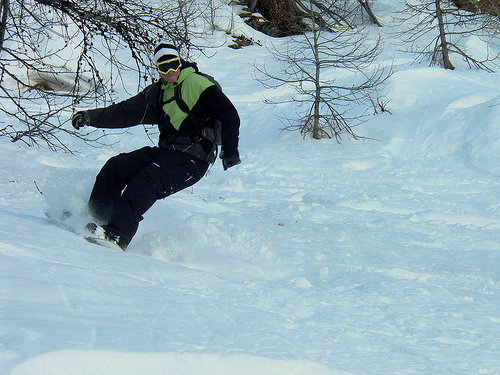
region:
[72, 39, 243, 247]
man on snow board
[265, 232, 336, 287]
white snow on hill side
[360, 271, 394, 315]
white snow on hill side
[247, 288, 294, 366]
white snow on hill side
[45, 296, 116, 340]
white snow on hill side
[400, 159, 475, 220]
white snow on hill side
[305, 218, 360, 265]
white snow on hill side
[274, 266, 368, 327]
white snow on hill side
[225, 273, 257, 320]
white snow on hill side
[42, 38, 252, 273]
snow boarder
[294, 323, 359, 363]
white snow on hill side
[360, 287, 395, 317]
white snow on hill side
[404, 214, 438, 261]
white snow on hill side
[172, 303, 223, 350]
white snow on hill side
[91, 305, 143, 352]
white snow on hill side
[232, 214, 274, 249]
white snow on hill side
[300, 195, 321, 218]
white snow on hill side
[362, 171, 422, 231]
white snow on hill side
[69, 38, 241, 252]
a skier dressed in mostly black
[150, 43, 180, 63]
a blue and white ski hat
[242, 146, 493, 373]
white drifting snow, good for sking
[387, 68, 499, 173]
a white snow drift in background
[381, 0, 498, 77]
a tree in the winter time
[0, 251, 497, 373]
drifting snow, good to ski on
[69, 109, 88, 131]
a black gloved skier's hand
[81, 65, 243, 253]
a black with green skiers outfit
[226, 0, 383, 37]
a bare tree trunk amidst the snow drifts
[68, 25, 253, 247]
young man on snow board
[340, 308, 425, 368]
white snow on hill side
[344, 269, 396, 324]
white snow on hill side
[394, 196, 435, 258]
white snow on hill side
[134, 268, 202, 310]
white snow on hill side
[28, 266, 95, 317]
white snow on hill side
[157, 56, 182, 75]
The yellow and black snow glasses.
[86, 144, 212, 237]
The black snow pants.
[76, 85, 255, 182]
The mans black and green coat.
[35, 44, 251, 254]
man riding snowboard in white snow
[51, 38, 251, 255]
person riding snowboard in white snow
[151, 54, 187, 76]
man wearing black and yellow goggles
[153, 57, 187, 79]
black and yellow goggles worn by man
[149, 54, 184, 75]
black and yellow goggles worn by snowboarder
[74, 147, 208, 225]
black pants worn by man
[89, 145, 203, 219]
black pants worn by snowboarder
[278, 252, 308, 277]
white snow on hill side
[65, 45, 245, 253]
Man in a green and black jacket skiing.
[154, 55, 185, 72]
Goggles on a man skiing in the snow.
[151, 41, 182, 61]
Black and white hat on a man skiing.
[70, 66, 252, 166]
Black and green jacket on a man skiing.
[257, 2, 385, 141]
Leafless tree to the right of the skier.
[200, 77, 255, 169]
Left arm of a man skiing.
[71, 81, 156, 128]
Right arm of a man skiing.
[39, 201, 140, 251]
Skis and feet of a man skiing.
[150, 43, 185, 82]
Head of a man skiing in a green jacket.